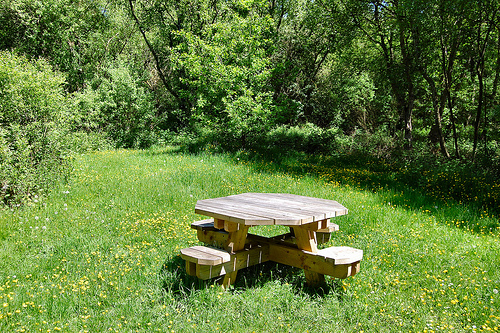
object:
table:
[179, 192, 365, 291]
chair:
[179, 245, 231, 266]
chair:
[301, 246, 366, 265]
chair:
[190, 219, 215, 231]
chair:
[317, 220, 341, 234]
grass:
[0, 142, 499, 333]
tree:
[409, 0, 451, 158]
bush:
[0, 46, 73, 211]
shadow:
[234, 260, 295, 291]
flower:
[425, 209, 429, 212]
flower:
[387, 201, 393, 207]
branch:
[378, 2, 399, 18]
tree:
[355, 0, 425, 150]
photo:
[0, 0, 498, 333]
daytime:
[0, 2, 499, 332]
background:
[2, 0, 499, 204]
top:
[194, 193, 349, 226]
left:
[0, 1, 243, 332]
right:
[241, 0, 499, 332]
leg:
[305, 272, 325, 289]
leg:
[222, 271, 239, 288]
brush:
[253, 122, 344, 152]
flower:
[83, 275, 88, 279]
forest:
[0, 0, 500, 218]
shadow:
[174, 139, 497, 236]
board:
[195, 203, 275, 224]